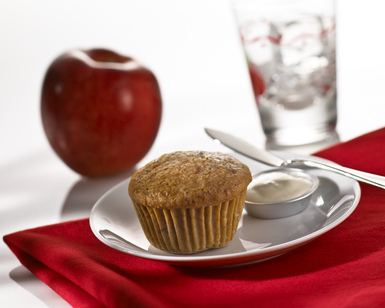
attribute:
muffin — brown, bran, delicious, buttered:
[127, 152, 253, 254]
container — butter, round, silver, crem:
[243, 165, 321, 219]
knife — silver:
[204, 126, 384, 188]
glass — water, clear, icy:
[234, 1, 340, 149]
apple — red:
[41, 44, 163, 182]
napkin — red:
[4, 127, 383, 307]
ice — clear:
[243, 19, 281, 68]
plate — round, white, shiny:
[89, 149, 361, 268]